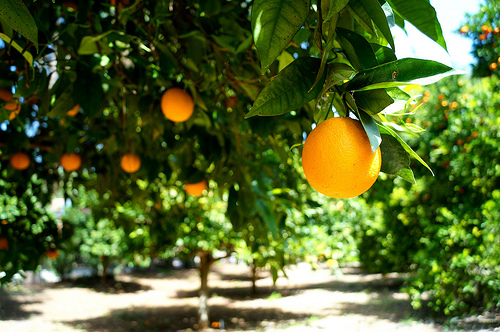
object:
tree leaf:
[243, 53, 330, 118]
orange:
[120, 153, 139, 171]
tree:
[0, 0, 453, 279]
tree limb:
[210, 45, 249, 93]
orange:
[46, 246, 58, 258]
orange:
[2, 237, 9, 249]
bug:
[391, 68, 399, 83]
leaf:
[337, 58, 453, 93]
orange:
[301, 116, 382, 198]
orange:
[58, 153, 80, 170]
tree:
[0, 175, 59, 282]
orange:
[160, 87, 193, 122]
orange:
[457, 24, 471, 36]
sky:
[380, 0, 490, 87]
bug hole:
[387, 70, 400, 80]